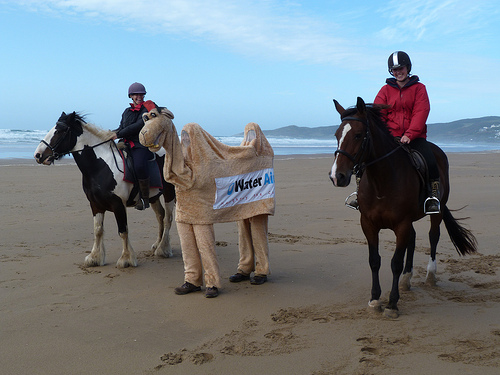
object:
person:
[344, 49, 441, 218]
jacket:
[369, 80, 433, 141]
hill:
[432, 115, 498, 140]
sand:
[0, 267, 116, 373]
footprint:
[189, 352, 211, 365]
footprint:
[357, 335, 375, 345]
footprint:
[359, 356, 371, 368]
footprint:
[160, 352, 183, 365]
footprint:
[312, 317, 330, 325]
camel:
[136, 107, 278, 299]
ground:
[276, 155, 328, 286]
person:
[106, 80, 172, 209]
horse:
[34, 110, 177, 269]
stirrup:
[422, 195, 442, 215]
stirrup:
[343, 190, 363, 212]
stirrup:
[134, 192, 152, 210]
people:
[137, 118, 223, 300]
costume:
[138, 106, 276, 287]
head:
[315, 89, 383, 192]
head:
[28, 107, 88, 172]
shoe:
[172, 280, 204, 295]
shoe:
[201, 283, 223, 300]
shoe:
[249, 269, 269, 286]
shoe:
[230, 267, 250, 285]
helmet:
[384, 51, 415, 74]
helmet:
[126, 82, 149, 98]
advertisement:
[210, 167, 278, 212]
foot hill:
[235, 109, 498, 143]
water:
[1, 141, 36, 156]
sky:
[0, 1, 382, 80]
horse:
[328, 95, 479, 319]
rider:
[367, 48, 443, 216]